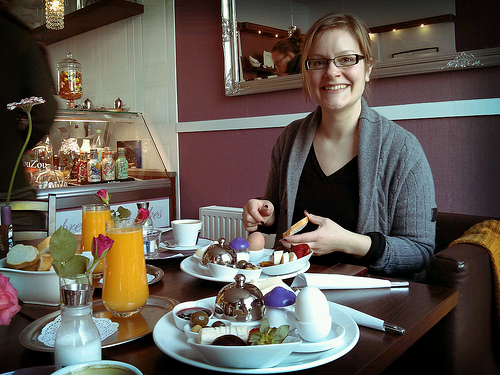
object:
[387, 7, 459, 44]
mirror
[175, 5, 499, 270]
wall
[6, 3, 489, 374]
building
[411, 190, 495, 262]
chair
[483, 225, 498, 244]
material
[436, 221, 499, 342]
armchair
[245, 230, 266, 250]
egg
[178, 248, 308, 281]
platter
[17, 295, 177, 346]
platter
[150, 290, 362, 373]
platter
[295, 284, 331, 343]
egg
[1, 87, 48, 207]
flower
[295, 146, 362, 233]
shirt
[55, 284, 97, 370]
milk jar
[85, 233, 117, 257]
flower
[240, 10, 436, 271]
woman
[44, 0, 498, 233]
wall